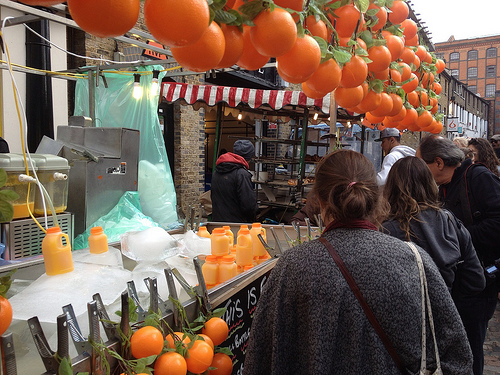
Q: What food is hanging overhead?
A: Oranges.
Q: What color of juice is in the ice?
A: Orange.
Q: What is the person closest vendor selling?
A: Fresh orange juice.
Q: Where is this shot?
A: Street.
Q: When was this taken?
A: Daytime.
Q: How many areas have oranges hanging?
A: 2.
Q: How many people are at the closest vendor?
A: 3.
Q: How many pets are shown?
A: 0.